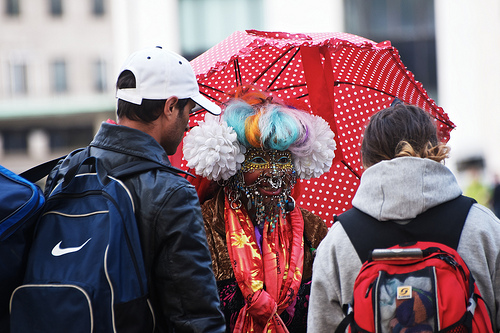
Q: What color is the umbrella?
A: Red.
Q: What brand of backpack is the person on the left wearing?
A: Nike.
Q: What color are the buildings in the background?
A: White.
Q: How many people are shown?
A: Three.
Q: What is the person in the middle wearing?
A: Wig.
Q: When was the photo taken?
A: Daytime.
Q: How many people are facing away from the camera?
A: Two.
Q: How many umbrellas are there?
A: One.